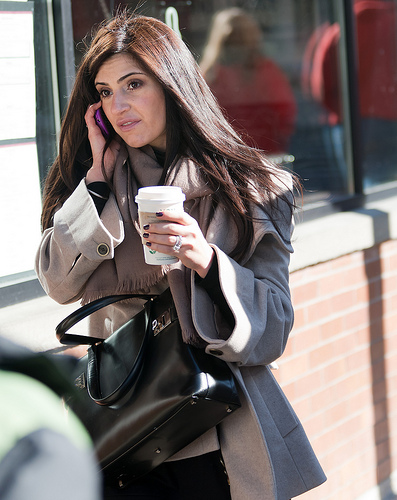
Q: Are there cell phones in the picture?
A: Yes, there is a cell phone.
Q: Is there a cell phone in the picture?
A: Yes, there is a cell phone.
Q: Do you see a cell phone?
A: Yes, there is a cell phone.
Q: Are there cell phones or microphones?
A: Yes, there is a cell phone.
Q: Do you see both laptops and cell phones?
A: No, there is a cell phone but no laptops.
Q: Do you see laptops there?
A: No, there are no laptops.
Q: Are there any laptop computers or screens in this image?
A: No, there are no laptop computers or screens.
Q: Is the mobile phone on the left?
A: Yes, the mobile phone is on the left of the image.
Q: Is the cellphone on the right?
A: No, the cellphone is on the left of the image.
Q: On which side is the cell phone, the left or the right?
A: The cell phone is on the left of the image.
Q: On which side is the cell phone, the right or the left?
A: The cell phone is on the left of the image.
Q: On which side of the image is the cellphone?
A: The cellphone is on the left of the image.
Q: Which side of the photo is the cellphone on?
A: The cellphone is on the left of the image.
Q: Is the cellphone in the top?
A: Yes, the cellphone is in the top of the image.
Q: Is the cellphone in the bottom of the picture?
A: No, the cellphone is in the top of the image.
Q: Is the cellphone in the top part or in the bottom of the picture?
A: The cellphone is in the top of the image.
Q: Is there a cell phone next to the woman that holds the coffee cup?
A: Yes, there is a cell phone next to the woman.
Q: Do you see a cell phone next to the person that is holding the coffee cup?
A: Yes, there is a cell phone next to the woman.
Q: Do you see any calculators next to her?
A: No, there is a cell phone next to the woman.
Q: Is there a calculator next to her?
A: No, there is a cell phone next to the woman.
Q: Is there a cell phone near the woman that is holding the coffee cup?
A: Yes, there is a cell phone near the woman.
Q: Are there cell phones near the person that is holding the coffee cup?
A: Yes, there is a cell phone near the woman.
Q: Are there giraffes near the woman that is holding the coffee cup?
A: No, there is a cell phone near the woman.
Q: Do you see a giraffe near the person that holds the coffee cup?
A: No, there is a cell phone near the woman.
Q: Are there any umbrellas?
A: No, there are no umbrellas.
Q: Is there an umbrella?
A: No, there are no umbrellas.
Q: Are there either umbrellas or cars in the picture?
A: No, there are no umbrellas or cars.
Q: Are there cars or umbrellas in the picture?
A: No, there are no umbrellas or cars.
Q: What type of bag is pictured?
A: The bag is a handbag.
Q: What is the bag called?
A: The bag is a handbag.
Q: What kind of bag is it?
A: The bag is a handbag.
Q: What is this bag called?
A: This is a handbag.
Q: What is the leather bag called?
A: The bag is a handbag.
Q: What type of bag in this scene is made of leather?
A: The bag is a handbag.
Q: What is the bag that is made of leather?
A: The bag is a handbag.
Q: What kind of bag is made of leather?
A: The bag is a handbag.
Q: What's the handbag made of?
A: The handbag is made of leather.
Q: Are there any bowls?
A: No, there are no bowls.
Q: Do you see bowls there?
A: No, there are no bowls.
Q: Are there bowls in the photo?
A: No, there are no bowls.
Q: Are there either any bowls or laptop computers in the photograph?
A: No, there are no bowls or laptop computers.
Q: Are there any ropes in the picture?
A: No, there are no ropes.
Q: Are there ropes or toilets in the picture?
A: No, there are no ropes or toilets.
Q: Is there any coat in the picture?
A: Yes, there is a coat.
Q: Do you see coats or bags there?
A: Yes, there is a coat.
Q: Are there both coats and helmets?
A: No, there is a coat but no helmets.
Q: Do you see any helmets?
A: No, there are no helmets.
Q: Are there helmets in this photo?
A: No, there are no helmets.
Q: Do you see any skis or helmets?
A: No, there are no helmets or skis.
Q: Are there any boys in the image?
A: No, there are no boys.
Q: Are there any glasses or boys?
A: No, there are no boys or glasses.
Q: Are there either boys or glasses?
A: No, there are no boys or glasses.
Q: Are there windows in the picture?
A: Yes, there is a window.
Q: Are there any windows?
A: Yes, there is a window.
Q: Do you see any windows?
A: Yes, there is a window.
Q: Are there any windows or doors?
A: Yes, there is a window.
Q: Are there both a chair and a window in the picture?
A: No, there is a window but no chairs.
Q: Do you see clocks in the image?
A: No, there are no clocks.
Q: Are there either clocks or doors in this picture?
A: No, there are no clocks or doors.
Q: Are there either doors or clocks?
A: No, there are no clocks or doors.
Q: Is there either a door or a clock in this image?
A: No, there are no clocks or doors.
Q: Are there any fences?
A: No, there are no fences.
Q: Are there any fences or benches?
A: No, there are no fences or benches.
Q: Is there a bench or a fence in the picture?
A: No, there are no fences or benches.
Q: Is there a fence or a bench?
A: No, there are no fences or benches.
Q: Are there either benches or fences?
A: No, there are no fences or benches.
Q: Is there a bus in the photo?
A: No, there are no buses.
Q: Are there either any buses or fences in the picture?
A: No, there are no buses or fences.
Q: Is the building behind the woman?
A: Yes, the building is behind the woman.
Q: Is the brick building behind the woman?
A: Yes, the building is behind the woman.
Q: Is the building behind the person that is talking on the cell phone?
A: Yes, the building is behind the woman.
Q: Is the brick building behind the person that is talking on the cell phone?
A: Yes, the building is behind the woman.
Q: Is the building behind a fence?
A: No, the building is behind the woman.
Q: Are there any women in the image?
A: Yes, there is a woman.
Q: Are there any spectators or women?
A: Yes, there is a woman.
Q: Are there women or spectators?
A: Yes, there is a woman.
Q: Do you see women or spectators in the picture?
A: Yes, there is a woman.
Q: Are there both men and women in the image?
A: No, there is a woman but no men.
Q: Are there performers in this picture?
A: No, there are no performers.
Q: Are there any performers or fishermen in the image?
A: No, there are no performers or fishermen.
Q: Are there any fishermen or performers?
A: No, there are no performers or fishermen.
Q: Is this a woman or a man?
A: This is a woman.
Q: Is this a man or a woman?
A: This is a woman.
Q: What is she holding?
A: The woman is holding the coffee cup.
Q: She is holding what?
A: The woman is holding the coffee cup.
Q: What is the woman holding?
A: The woman is holding the coffee cup.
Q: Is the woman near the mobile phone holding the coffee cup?
A: Yes, the woman is holding the coffee cup.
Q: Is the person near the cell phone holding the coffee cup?
A: Yes, the woman is holding the coffee cup.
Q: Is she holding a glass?
A: No, the woman is holding the coffee cup.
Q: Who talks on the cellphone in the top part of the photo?
A: The woman talks on the mobile phone.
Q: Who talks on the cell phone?
A: The woman talks on the mobile phone.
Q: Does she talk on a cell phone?
A: Yes, the woman talks on a cell phone.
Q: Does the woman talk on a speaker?
A: No, the woman talks on a cell phone.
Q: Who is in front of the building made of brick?
A: The woman is in front of the building.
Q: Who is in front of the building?
A: The woman is in front of the building.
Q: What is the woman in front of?
A: The woman is in front of the building.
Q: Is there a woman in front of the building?
A: Yes, there is a woman in front of the building.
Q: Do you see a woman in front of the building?
A: Yes, there is a woman in front of the building.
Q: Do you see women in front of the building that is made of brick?
A: Yes, there is a woman in front of the building.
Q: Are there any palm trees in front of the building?
A: No, there is a woman in front of the building.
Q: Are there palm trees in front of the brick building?
A: No, there is a woman in front of the building.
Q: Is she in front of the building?
A: Yes, the woman is in front of the building.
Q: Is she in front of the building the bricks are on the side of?
A: Yes, the woman is in front of the building.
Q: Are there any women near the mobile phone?
A: Yes, there is a woman near the mobile phone.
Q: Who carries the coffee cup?
A: The woman carries the coffee cup.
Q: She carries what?
A: The woman carries a coffee cup.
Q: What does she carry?
A: The woman carries a coffee cup.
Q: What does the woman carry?
A: The woman carries a coffee cup.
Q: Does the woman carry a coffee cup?
A: Yes, the woman carries a coffee cup.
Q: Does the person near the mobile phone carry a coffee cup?
A: Yes, the woman carries a coffee cup.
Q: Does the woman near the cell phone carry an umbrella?
A: No, the woman carries a coffee cup.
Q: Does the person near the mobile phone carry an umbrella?
A: No, the woman carries a coffee cup.